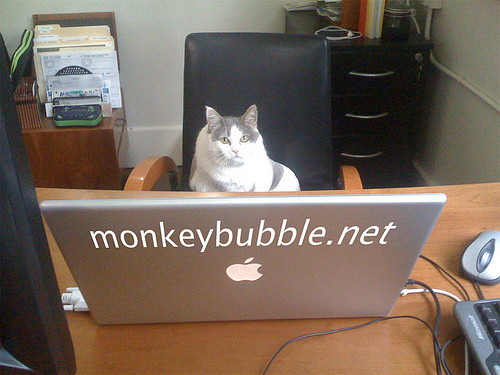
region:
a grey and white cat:
[167, 88, 308, 198]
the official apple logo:
[215, 251, 273, 291]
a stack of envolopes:
[34, 8, 122, 118]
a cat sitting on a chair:
[168, 14, 343, 194]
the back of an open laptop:
[38, 175, 446, 329]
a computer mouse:
[455, 218, 497, 288]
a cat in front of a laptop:
[47, 85, 435, 340]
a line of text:
[75, 218, 406, 253]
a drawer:
[291, 5, 425, 162]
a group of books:
[327, 0, 428, 42]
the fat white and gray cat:
[188, 105, 301, 192]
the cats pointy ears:
[205, 102, 259, 125]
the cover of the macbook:
[47, 199, 404, 319]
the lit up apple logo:
[225, 255, 262, 282]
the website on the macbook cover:
[87, 220, 394, 245]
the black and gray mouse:
[462, 227, 498, 280]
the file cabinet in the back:
[293, 5, 431, 175]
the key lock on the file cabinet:
[411, 52, 425, 81]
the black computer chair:
[128, 33, 363, 197]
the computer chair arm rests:
[126, 152, 363, 195]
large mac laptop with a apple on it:
[40, 161, 470, 342]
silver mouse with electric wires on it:
[451, 212, 498, 289]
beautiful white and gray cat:
[151, 110, 337, 206]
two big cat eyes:
[190, 100, 312, 153]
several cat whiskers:
[180, 101, 266, 180]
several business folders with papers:
[16, 17, 136, 133]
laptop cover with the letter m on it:
[62, 195, 453, 275]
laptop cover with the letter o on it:
[62, 206, 395, 277]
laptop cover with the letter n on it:
[82, 217, 438, 284]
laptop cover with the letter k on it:
[57, 210, 405, 272]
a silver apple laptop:
[36, 191, 448, 326]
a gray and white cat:
[186, 105, 302, 194]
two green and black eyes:
[219, 135, 251, 145]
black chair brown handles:
[121, 30, 365, 192]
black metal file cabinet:
[327, 32, 434, 186]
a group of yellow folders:
[29, 23, 124, 107]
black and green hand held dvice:
[48, 101, 107, 128]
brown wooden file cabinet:
[13, 70, 132, 189]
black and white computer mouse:
[460, 226, 499, 285]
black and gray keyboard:
[455, 293, 498, 374]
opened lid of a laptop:
[55, 192, 429, 320]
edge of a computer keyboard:
[456, 279, 498, 373]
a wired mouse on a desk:
[457, 220, 498, 289]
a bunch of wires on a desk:
[417, 252, 462, 364]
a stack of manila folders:
[30, 20, 118, 67]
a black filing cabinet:
[330, 42, 429, 182]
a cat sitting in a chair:
[175, 102, 305, 195]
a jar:
[380, 1, 422, 44]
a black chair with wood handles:
[140, 26, 363, 194]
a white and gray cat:
[188, 96, 313, 196]